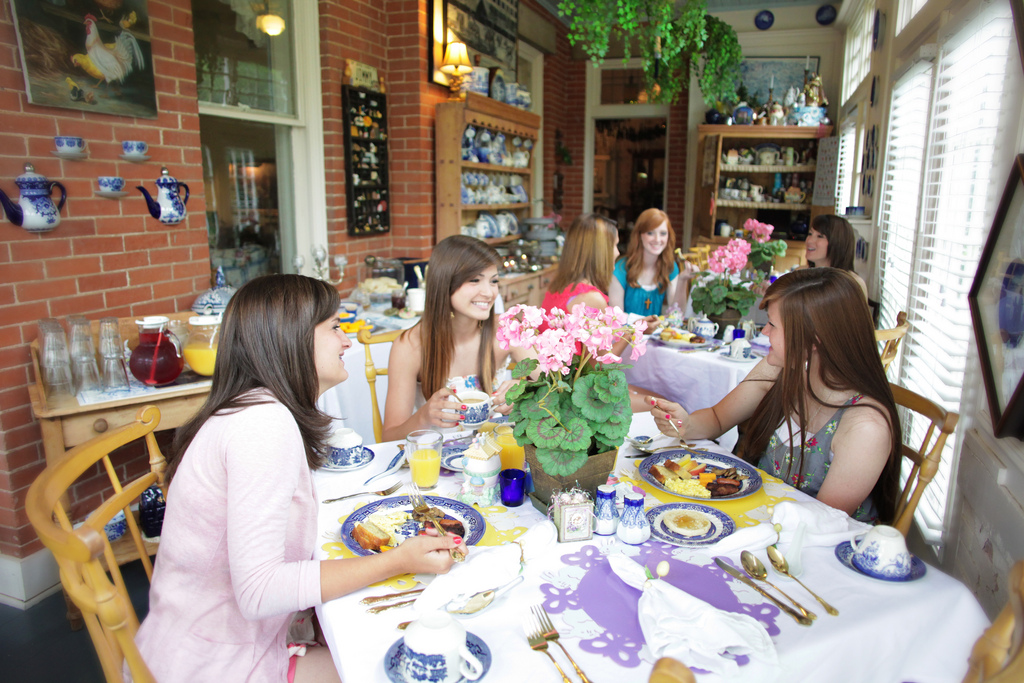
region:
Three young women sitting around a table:
[122, 213, 999, 676]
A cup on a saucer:
[826, 513, 931, 589]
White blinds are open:
[857, 1, 1016, 558]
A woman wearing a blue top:
[599, 194, 685, 325]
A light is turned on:
[427, 24, 485, 91]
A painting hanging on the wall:
[1, 0, 166, 133]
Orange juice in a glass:
[390, 418, 452, 495]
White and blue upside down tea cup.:
[846, 516, 917, 581]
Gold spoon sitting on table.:
[762, 540, 835, 618]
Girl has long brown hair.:
[758, 266, 910, 485]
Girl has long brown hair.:
[414, 231, 510, 375]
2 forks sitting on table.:
[518, 603, 580, 680]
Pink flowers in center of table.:
[493, 298, 627, 391]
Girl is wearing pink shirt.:
[547, 266, 602, 325]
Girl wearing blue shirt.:
[615, 253, 686, 315]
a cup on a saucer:
[377, 606, 498, 679]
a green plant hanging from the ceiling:
[539, 4, 764, 122]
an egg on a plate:
[643, 494, 739, 555]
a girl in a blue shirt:
[608, 197, 686, 330]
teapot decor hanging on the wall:
[125, 160, 203, 233]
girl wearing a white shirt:
[128, 265, 473, 678]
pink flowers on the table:
[694, 210, 784, 287]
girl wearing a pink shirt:
[536, 205, 625, 342]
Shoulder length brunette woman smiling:
[130, 265, 372, 680]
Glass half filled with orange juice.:
[397, 424, 454, 494]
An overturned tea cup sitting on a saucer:
[834, 518, 930, 580]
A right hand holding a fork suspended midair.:
[401, 486, 469, 575]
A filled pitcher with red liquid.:
[130, 307, 185, 388]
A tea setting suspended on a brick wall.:
[2, 127, 196, 233]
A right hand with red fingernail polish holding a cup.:
[424, 380, 492, 429]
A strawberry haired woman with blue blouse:
[616, 200, 684, 312]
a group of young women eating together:
[131, 149, 945, 652]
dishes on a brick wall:
[0, 126, 203, 248]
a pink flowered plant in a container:
[484, 282, 653, 552]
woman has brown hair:
[173, 246, 351, 474]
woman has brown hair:
[411, 224, 509, 409]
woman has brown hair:
[720, 262, 927, 500]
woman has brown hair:
[793, 202, 866, 283]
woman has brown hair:
[556, 212, 632, 296]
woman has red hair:
[629, 198, 686, 296]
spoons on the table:
[704, 541, 828, 640]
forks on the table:
[518, 591, 596, 678]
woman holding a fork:
[401, 476, 478, 576]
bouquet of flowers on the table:
[487, 279, 633, 501]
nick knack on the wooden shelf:
[454, 119, 477, 152]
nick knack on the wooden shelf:
[478, 131, 491, 157]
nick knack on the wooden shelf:
[491, 134, 520, 183]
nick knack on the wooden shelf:
[459, 169, 473, 188]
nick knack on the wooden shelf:
[718, 166, 728, 202]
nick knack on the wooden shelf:
[721, 138, 738, 165]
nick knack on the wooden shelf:
[781, 141, 800, 171]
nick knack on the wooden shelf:
[769, 172, 785, 191]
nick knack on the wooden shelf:
[763, 89, 793, 129]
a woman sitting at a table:
[164, 270, 352, 679]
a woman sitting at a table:
[391, 207, 505, 422]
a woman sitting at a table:
[679, 275, 904, 498]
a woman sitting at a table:
[554, 221, 606, 326]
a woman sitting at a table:
[615, 206, 691, 323]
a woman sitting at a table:
[788, 213, 865, 290]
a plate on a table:
[344, 494, 471, 552]